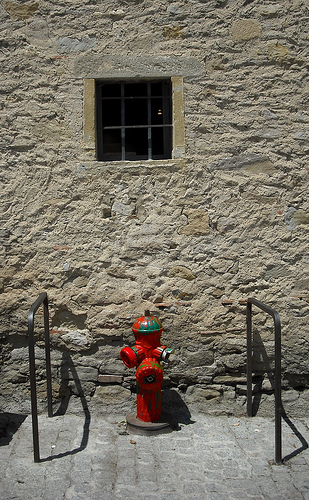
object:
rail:
[246, 297, 283, 464]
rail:
[27, 290, 54, 463]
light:
[159, 109, 162, 111]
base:
[125, 409, 171, 430]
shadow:
[39, 351, 92, 464]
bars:
[102, 124, 172, 130]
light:
[158, 112, 163, 116]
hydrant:
[119, 307, 177, 424]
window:
[94, 76, 173, 161]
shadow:
[138, 368, 197, 432]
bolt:
[144, 309, 150, 316]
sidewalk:
[0, 407, 309, 500]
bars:
[98, 84, 104, 158]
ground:
[0, 414, 309, 497]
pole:
[274, 311, 282, 467]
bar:
[148, 83, 153, 160]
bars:
[101, 96, 171, 99]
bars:
[121, 81, 126, 160]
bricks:
[177, 439, 198, 466]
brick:
[64, 380, 96, 397]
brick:
[57, 364, 98, 383]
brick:
[97, 373, 123, 384]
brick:
[213, 373, 256, 384]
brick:
[235, 383, 256, 395]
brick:
[177, 383, 188, 392]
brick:
[10, 373, 28, 385]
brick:
[99, 359, 128, 375]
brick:
[220, 352, 247, 375]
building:
[0, 0, 307, 421]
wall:
[0, 0, 309, 417]